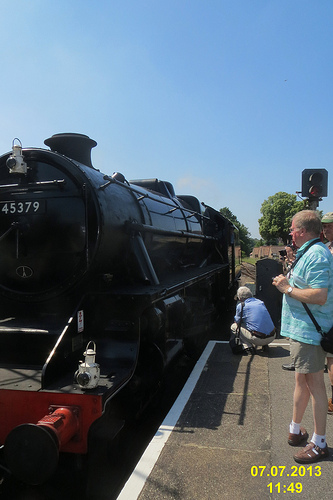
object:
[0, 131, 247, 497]
old locomotive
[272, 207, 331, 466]
guy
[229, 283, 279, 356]
gray man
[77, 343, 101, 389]
white lamp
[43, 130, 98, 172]
stack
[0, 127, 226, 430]
locomotive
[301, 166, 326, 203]
signal light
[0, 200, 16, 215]
first two/numbers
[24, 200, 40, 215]
last two/numbers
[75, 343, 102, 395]
light structure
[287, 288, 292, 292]
watch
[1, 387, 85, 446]
paint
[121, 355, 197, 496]
line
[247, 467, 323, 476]
date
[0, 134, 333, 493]
photo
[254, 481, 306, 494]
time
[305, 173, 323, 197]
light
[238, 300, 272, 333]
shirt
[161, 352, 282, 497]
platform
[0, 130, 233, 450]
train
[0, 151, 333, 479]
station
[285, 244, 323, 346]
bag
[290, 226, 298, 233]
glasses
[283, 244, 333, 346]
shirt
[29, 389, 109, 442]
bumper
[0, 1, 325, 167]
skies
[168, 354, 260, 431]
shadow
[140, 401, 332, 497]
asphalt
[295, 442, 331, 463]
sandals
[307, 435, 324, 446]
socks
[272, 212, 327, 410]
man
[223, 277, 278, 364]
man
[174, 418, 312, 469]
line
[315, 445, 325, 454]
buckle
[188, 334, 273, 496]
pavement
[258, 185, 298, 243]
trees